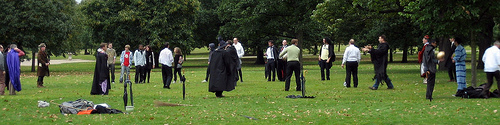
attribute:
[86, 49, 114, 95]
garment — long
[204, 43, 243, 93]
robe — black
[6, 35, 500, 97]
person — wearing, adjusting, starting, walking, standing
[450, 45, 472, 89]
jumpsuit — blue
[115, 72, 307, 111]
umbrella — stuck, sticking, sticked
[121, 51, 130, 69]
shirt — red, white, black, yellow, green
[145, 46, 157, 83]
girl — carrying, wearing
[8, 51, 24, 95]
clothes — blue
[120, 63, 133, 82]
jean — blue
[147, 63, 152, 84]
pant — black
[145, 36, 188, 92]
woman — wearing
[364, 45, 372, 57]
car — red